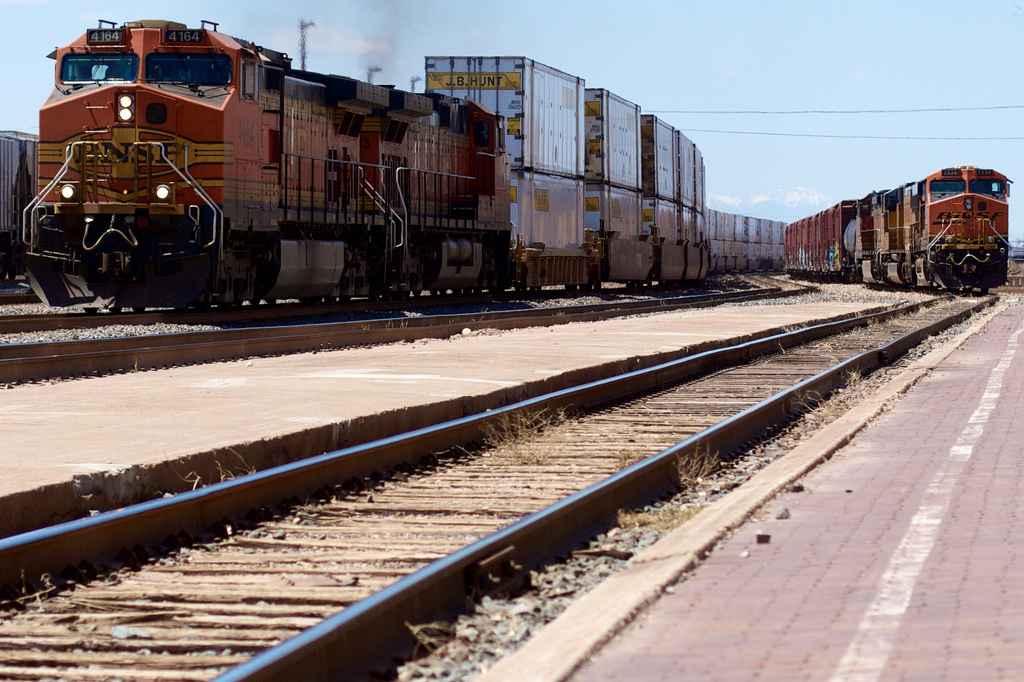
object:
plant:
[477, 397, 594, 466]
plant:
[673, 436, 723, 491]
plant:
[841, 366, 865, 392]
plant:
[162, 446, 257, 491]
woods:
[0, 531, 499, 681]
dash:
[822, 329, 1024, 682]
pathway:
[468, 299, 1024, 681]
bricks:
[679, 581, 841, 661]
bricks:
[947, 504, 1023, 680]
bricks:
[955, 349, 987, 386]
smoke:
[356, 0, 410, 85]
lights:
[120, 95, 133, 120]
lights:
[964, 197, 973, 210]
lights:
[61, 186, 74, 198]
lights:
[156, 187, 169, 199]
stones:
[740, 483, 805, 557]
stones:
[386, 546, 652, 682]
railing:
[0, 292, 1000, 681]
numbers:
[88, 30, 203, 43]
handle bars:
[359, 167, 409, 261]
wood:
[0, 599, 343, 682]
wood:
[600, 383, 806, 416]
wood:
[712, 357, 852, 378]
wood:
[405, 455, 646, 481]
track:
[0, 294, 1004, 682]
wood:
[855, 321, 938, 328]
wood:
[142, 519, 509, 573]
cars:
[22, 20, 788, 296]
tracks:
[2, 272, 818, 384]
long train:
[785, 165, 1015, 297]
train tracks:
[0, 293, 999, 682]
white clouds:
[844, 61, 956, 105]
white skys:
[788, 0, 1024, 94]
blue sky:
[0, 1, 1024, 242]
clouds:
[619, 25, 794, 77]